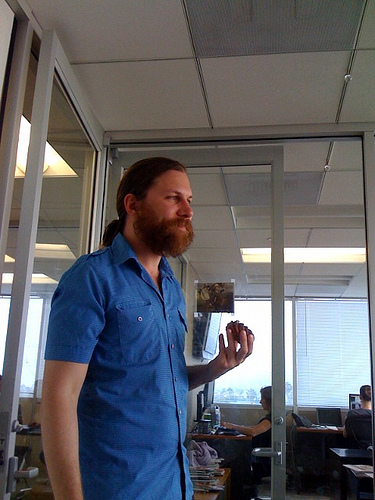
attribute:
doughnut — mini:
[212, 317, 276, 339]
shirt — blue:
[40, 255, 204, 451]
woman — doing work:
[245, 378, 284, 468]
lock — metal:
[265, 412, 292, 428]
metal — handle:
[246, 443, 291, 462]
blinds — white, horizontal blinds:
[285, 290, 365, 405]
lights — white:
[237, 239, 364, 278]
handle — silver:
[248, 439, 311, 479]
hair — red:
[137, 208, 172, 257]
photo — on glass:
[180, 269, 275, 326]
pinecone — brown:
[190, 420, 206, 437]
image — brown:
[191, 274, 255, 324]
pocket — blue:
[107, 293, 169, 375]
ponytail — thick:
[98, 211, 127, 249]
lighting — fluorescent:
[6, 110, 86, 188]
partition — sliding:
[294, 438, 360, 469]